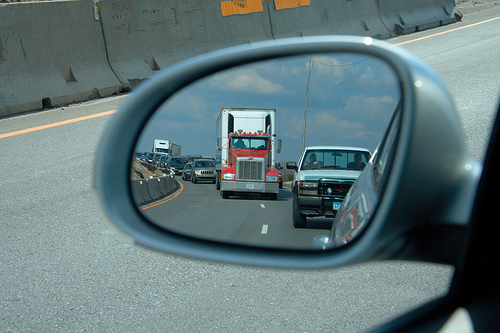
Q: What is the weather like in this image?
A: It is cloudy.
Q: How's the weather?
A: It is cloudy.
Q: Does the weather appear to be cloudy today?
A: Yes, it is cloudy.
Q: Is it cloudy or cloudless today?
A: It is cloudy.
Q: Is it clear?
A: No, it is cloudy.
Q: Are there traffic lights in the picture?
A: No, there are no traffic lights.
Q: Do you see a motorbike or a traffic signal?
A: No, there are no traffic lights or motorcycles.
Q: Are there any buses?
A: No, there are no buses.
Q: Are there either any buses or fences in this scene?
A: No, there are no buses or fences.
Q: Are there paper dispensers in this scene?
A: No, there are no paper dispensers.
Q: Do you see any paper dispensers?
A: No, there are no paper dispensers.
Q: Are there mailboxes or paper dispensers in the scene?
A: No, there are no paper dispensers or mailboxes.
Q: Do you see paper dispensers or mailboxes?
A: No, there are no paper dispensers or mailboxes.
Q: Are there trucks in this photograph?
A: Yes, there is a truck.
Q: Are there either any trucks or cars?
A: Yes, there is a truck.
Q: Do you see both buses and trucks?
A: No, there is a truck but no buses.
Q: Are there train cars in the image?
A: No, there are no train cars.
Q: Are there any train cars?
A: No, there are no train cars.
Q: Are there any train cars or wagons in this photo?
A: No, there are no train cars or wagons.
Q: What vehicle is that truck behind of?
A: The truck is behind the car.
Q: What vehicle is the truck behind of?
A: The truck is behind the car.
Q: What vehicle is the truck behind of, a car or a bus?
A: The truck is behind a car.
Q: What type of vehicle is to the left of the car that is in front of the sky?
A: The vehicle is a truck.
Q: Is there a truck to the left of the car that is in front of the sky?
A: Yes, there is a truck to the left of the car.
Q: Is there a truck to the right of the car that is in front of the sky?
A: No, the truck is to the left of the car.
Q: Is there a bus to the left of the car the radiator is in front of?
A: No, there is a truck to the left of the car.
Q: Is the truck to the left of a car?
A: Yes, the truck is to the left of a car.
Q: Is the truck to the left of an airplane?
A: No, the truck is to the left of a car.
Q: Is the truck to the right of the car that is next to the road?
A: No, the truck is to the left of the car.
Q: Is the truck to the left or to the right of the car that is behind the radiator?
A: The truck is to the left of the car.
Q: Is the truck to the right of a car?
A: Yes, the truck is to the right of a car.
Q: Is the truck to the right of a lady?
A: No, the truck is to the right of a car.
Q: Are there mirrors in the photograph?
A: Yes, there is a mirror.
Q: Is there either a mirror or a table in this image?
A: Yes, there is a mirror.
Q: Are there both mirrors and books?
A: No, there is a mirror but no books.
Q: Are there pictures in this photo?
A: No, there are no pictures.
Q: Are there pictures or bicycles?
A: No, there are no pictures or bicycles.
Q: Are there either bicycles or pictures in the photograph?
A: No, there are no pictures or bicycles.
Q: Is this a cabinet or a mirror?
A: This is a mirror.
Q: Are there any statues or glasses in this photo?
A: No, there are no glasses or statues.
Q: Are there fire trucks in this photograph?
A: No, there are no fire trucks.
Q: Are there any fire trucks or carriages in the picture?
A: No, there are no fire trucks or carriages.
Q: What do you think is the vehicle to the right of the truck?
A: The vehicle is a car.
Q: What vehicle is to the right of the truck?
A: The vehicle is a car.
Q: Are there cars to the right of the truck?
A: Yes, there is a car to the right of the truck.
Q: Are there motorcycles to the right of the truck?
A: No, there is a car to the right of the truck.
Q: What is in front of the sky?
A: The car is in front of the sky.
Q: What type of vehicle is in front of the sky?
A: The vehicle is a car.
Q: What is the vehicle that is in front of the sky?
A: The vehicle is a car.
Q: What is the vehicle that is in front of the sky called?
A: The vehicle is a car.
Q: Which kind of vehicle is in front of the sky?
A: The vehicle is a car.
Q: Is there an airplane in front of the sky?
A: No, there is a car in front of the sky.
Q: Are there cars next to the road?
A: Yes, there is a car next to the road.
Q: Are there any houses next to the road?
A: No, there is a car next to the road.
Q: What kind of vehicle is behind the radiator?
A: The vehicle is a car.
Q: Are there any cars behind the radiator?
A: Yes, there is a car behind the radiator.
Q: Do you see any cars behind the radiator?
A: Yes, there is a car behind the radiator.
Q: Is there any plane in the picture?
A: No, there are no airplanes.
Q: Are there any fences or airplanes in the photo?
A: No, there are no airplanes or fences.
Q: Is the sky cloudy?
A: Yes, the sky is cloudy.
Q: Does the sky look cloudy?
A: Yes, the sky is cloudy.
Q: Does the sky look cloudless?
A: No, the sky is cloudy.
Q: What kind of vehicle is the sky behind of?
A: The sky is behind the car.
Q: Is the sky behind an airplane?
A: No, the sky is behind the car.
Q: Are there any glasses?
A: No, there are no glasses.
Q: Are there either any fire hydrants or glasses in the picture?
A: No, there are no glasses or fire hydrants.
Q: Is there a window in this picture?
A: Yes, there is a window.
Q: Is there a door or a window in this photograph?
A: Yes, there is a window.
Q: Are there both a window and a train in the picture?
A: No, there is a window but no trains.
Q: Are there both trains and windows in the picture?
A: No, there is a window but no trains.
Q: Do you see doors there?
A: No, there are no doors.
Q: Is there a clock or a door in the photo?
A: No, there are no doors or clocks.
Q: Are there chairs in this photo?
A: No, there are no chairs.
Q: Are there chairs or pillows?
A: No, there are no chairs or pillows.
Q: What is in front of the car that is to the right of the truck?
A: The radiator is in front of the car.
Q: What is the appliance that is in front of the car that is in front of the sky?
A: The appliance is a radiator.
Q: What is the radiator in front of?
A: The radiator is in front of the car.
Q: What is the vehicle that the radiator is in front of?
A: The vehicle is a car.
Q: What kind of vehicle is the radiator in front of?
A: The radiator is in front of the car.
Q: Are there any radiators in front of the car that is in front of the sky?
A: Yes, there is a radiator in front of the car.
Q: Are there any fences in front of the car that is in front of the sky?
A: No, there is a radiator in front of the car.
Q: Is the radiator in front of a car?
A: Yes, the radiator is in front of a car.